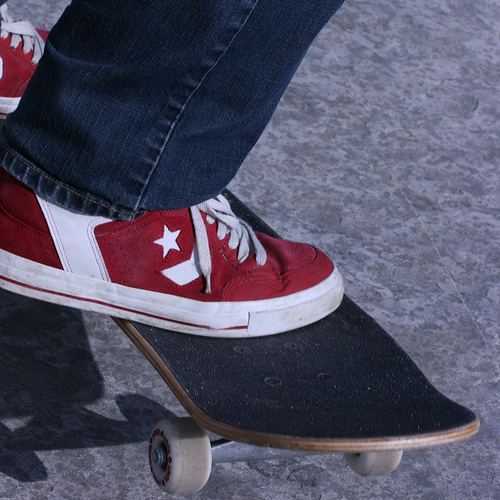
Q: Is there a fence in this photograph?
A: No, there are no fences.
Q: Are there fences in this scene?
A: No, there are no fences.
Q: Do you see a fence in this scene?
A: No, there are no fences.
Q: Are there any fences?
A: No, there are no fences.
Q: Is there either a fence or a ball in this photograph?
A: No, there are no fences or balls.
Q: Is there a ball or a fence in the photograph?
A: No, there are no fences or balls.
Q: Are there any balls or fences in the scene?
A: No, there are no fences or balls.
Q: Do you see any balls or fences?
A: No, there are no fences or balls.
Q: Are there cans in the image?
A: No, there are no cans.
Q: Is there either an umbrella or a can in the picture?
A: No, there are no cans or umbrellas.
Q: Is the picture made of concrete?
A: Yes, the picture is made of concrete.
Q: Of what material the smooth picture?
A: The picture is made of concrete.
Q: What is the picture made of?
A: The picture is made of concrete.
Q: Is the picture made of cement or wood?
A: The picture is made of cement.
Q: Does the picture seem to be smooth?
A: Yes, the picture is smooth.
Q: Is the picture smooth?
A: Yes, the picture is smooth.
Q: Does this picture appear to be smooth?
A: Yes, the picture is smooth.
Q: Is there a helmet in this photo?
A: No, there are no helmets.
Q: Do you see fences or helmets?
A: No, there are no helmets or fences.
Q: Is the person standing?
A: Yes, the person is standing.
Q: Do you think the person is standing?
A: Yes, the person is standing.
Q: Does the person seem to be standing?
A: Yes, the person is standing.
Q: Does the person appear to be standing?
A: Yes, the person is standing.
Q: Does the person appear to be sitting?
A: No, the person is standing.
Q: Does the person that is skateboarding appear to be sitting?
A: No, the person is standing.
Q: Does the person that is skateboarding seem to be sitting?
A: No, the person is standing.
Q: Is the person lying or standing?
A: The person is standing.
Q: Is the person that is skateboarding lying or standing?
A: The person is standing.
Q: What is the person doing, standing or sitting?
A: The person is standing.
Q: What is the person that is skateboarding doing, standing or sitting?
A: The person is standing.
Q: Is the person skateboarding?
A: Yes, the person is skateboarding.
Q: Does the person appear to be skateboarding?
A: Yes, the person is skateboarding.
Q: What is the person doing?
A: The person is skateboarding.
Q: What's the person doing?
A: The person is skateboarding.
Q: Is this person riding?
A: No, the person is skateboarding.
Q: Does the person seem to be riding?
A: No, the person is skateboarding.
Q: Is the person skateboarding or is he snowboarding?
A: The person is skateboarding.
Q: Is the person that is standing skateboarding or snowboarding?
A: The person is skateboarding.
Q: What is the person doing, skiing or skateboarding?
A: The person is skateboarding.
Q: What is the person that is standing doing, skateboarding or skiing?
A: The person is skateboarding.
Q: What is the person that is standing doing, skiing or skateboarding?
A: The person is skateboarding.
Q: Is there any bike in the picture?
A: No, there are no bikes.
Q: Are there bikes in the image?
A: No, there are no bikes.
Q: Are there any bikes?
A: No, there are no bikes.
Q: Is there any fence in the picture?
A: No, there are no fences.